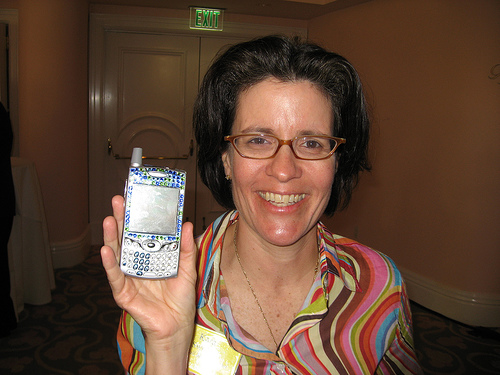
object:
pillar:
[8, 23, 88, 274]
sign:
[185, 2, 224, 33]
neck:
[236, 222, 314, 267]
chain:
[227, 230, 280, 349]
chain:
[308, 250, 318, 297]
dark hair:
[186, 31, 378, 210]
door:
[89, 29, 201, 261]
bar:
[130, 144, 143, 165]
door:
[11, 13, 52, 348]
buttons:
[119, 238, 183, 278]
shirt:
[114, 219, 420, 370]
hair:
[194, 36, 368, 223]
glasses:
[224, 131, 345, 160]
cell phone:
[119, 147, 187, 279]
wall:
[376, 59, 446, 204]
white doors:
[82, 12, 307, 211]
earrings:
[219, 169, 237, 183]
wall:
[390, 0, 497, 217]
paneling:
[412, 268, 498, 328]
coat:
[1, 141, 57, 323]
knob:
[7, 150, 37, 173]